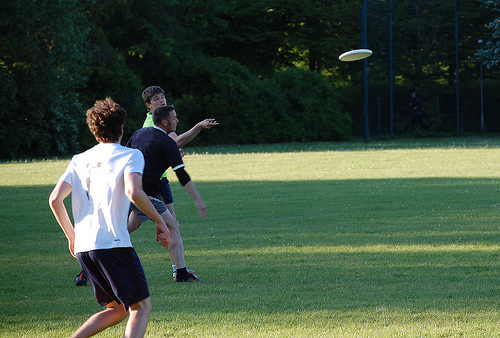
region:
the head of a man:
[59, 93, 140, 154]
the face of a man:
[158, 103, 185, 129]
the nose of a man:
[162, 105, 189, 132]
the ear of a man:
[147, 101, 181, 141]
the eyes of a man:
[149, 85, 170, 109]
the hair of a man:
[140, 88, 202, 135]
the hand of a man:
[177, 169, 241, 218]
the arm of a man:
[164, 95, 244, 158]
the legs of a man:
[89, 245, 174, 322]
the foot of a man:
[175, 234, 230, 304]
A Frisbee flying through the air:
[334, 42, 385, 69]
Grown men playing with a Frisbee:
[36, 58, 253, 332]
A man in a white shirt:
[41, 96, 162, 336]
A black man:
[127, 109, 206, 225]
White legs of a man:
[60, 289, 203, 335]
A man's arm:
[163, 111, 221, 149]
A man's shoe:
[156, 254, 210, 284]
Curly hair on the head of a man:
[77, 94, 134, 153]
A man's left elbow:
[41, 190, 70, 218]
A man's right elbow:
[124, 183, 164, 211]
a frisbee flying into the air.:
[321, 36, 386, 68]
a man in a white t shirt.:
[58, 131, 160, 269]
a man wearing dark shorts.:
[70, 241, 155, 315]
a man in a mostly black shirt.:
[124, 121, 185, 201]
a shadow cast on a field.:
[0, 173, 499, 323]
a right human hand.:
[171, 104, 223, 148]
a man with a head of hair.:
[79, 78, 136, 144]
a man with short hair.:
[146, 102, 186, 134]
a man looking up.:
[134, 81, 177, 112]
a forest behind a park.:
[0, 0, 498, 165]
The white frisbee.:
[329, 44, 375, 66]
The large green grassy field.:
[218, 154, 485, 329]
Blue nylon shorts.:
[74, 248, 150, 320]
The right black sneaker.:
[174, 264, 198, 284]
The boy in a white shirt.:
[57, 95, 145, 335]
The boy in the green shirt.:
[142, 82, 173, 126]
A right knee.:
[124, 291, 155, 317]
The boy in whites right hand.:
[156, 216, 176, 249]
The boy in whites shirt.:
[59, 138, 144, 255]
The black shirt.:
[132, 125, 172, 205]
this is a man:
[48, 38, 163, 319]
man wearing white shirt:
[48, 133, 175, 247]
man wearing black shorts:
[69, 228, 160, 312]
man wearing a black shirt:
[130, 117, 182, 195]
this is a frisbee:
[318, 21, 415, 115]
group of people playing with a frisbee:
[48, 30, 412, 322]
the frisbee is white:
[313, 25, 405, 96]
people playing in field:
[0, 64, 432, 331]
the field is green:
[20, 104, 455, 316]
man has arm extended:
[162, 107, 230, 152]